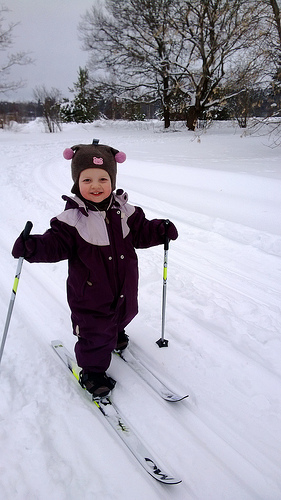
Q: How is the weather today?
A: It is foggy.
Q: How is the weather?
A: It is foggy.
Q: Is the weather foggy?
A: Yes, it is foggy.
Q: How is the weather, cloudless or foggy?
A: It is foggy.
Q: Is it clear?
A: No, it is foggy.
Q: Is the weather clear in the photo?
A: No, it is foggy.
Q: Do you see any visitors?
A: No, there are no visitors.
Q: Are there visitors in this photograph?
A: No, there are no visitors.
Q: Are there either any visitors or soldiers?
A: No, there are no visitors or soldiers.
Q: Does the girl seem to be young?
A: Yes, the girl is young.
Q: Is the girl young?
A: Yes, the girl is young.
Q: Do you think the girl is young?
A: Yes, the girl is young.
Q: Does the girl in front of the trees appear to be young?
A: Yes, the girl is young.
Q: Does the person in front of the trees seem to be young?
A: Yes, the girl is young.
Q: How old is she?
A: The girl is young.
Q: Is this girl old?
A: No, the girl is young.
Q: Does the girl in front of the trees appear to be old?
A: No, the girl is young.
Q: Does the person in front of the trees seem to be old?
A: No, the girl is young.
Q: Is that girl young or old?
A: The girl is young.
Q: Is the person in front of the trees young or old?
A: The girl is young.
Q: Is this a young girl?
A: Yes, this is a young girl.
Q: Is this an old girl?
A: No, this is a young girl.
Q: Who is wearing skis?
A: The girl is wearing skis.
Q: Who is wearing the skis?
A: The girl is wearing skis.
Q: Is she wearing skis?
A: Yes, the girl is wearing skis.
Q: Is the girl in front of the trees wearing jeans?
A: No, the girl is wearing skis.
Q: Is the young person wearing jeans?
A: No, the girl is wearing skis.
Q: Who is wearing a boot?
A: The girl is wearing a boot.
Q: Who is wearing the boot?
A: The girl is wearing a boot.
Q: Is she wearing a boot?
A: Yes, the girl is wearing a boot.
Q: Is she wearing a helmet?
A: No, the girl is wearing a boot.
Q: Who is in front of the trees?
A: The girl is in front of the trees.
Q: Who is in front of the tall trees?
A: The girl is in front of the trees.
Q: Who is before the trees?
A: The girl is in front of the trees.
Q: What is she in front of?
A: The girl is in front of the trees.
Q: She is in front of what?
A: The girl is in front of the trees.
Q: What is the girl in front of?
A: The girl is in front of the trees.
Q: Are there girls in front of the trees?
A: Yes, there is a girl in front of the trees.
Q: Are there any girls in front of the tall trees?
A: Yes, there is a girl in front of the trees.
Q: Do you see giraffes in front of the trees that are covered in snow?
A: No, there is a girl in front of the trees.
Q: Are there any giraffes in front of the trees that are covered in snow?
A: No, there is a girl in front of the trees.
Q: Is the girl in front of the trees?
A: Yes, the girl is in front of the trees.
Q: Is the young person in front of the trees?
A: Yes, the girl is in front of the trees.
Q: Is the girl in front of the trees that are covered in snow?
A: Yes, the girl is in front of the trees.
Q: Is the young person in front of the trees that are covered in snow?
A: Yes, the girl is in front of the trees.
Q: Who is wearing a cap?
A: The girl is wearing a cap.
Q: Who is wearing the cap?
A: The girl is wearing a cap.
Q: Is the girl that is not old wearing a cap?
A: Yes, the girl is wearing a cap.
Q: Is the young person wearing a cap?
A: Yes, the girl is wearing a cap.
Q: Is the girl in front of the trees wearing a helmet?
A: No, the girl is wearing a cap.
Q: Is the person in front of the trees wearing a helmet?
A: No, the girl is wearing a cap.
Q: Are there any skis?
A: Yes, there are skis.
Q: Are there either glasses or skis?
A: Yes, there are skis.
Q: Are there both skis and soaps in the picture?
A: No, there are skis but no soaps.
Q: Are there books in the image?
A: No, there are no books.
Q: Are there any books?
A: No, there are no books.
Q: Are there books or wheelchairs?
A: No, there are no books or wheelchairs.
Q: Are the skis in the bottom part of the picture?
A: Yes, the skis are in the bottom of the image.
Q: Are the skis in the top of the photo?
A: No, the skis are in the bottom of the image.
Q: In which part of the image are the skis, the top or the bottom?
A: The skis are in the bottom of the image.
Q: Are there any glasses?
A: No, there are no glasses.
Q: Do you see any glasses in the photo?
A: No, there are no glasses.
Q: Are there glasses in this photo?
A: No, there are no glasses.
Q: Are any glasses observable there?
A: No, there are no glasses.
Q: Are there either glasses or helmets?
A: No, there are no glasses or helmets.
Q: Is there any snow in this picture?
A: Yes, there is snow.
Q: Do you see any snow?
A: Yes, there is snow.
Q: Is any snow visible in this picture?
A: Yes, there is snow.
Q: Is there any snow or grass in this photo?
A: Yes, there is snow.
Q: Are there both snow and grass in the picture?
A: No, there is snow but no grass.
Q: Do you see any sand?
A: No, there is no sand.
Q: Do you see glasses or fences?
A: No, there are no fences or glasses.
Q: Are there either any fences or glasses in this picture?
A: No, there are no fences or glasses.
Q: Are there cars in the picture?
A: No, there are no cars.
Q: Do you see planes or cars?
A: No, there are no cars or planes.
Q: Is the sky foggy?
A: Yes, the sky is foggy.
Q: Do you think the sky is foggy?
A: Yes, the sky is foggy.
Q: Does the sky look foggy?
A: Yes, the sky is foggy.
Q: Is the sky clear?
A: No, the sky is foggy.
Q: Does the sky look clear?
A: No, the sky is foggy.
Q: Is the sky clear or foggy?
A: The sky is foggy.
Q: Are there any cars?
A: No, there are no cars.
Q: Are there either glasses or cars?
A: No, there are no cars or glasses.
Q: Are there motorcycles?
A: No, there are no motorcycles.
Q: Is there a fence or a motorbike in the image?
A: No, there are no motorcycles or fences.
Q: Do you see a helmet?
A: No, there are no helmets.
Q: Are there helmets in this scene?
A: No, there are no helmets.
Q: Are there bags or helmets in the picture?
A: No, there are no helmets or bags.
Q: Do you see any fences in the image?
A: No, there are no fences.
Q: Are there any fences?
A: No, there are no fences.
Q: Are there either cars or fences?
A: No, there are no fences or cars.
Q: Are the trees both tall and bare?
A: Yes, the trees are tall and bare.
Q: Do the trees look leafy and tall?
A: No, the trees are tall but bare.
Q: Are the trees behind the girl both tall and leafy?
A: No, the trees are tall but bare.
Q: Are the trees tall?
A: Yes, the trees are tall.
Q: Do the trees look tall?
A: Yes, the trees are tall.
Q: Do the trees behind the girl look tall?
A: Yes, the trees are tall.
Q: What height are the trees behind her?
A: The trees are tall.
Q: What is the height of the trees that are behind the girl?
A: The trees are tall.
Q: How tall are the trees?
A: The trees are tall.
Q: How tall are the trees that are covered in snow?
A: The trees are tall.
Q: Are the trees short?
A: No, the trees are tall.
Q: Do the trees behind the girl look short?
A: No, the trees are tall.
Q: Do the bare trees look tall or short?
A: The trees are tall.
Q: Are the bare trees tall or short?
A: The trees are tall.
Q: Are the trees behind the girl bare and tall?
A: Yes, the trees are bare and tall.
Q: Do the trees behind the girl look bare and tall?
A: Yes, the trees are bare and tall.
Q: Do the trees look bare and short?
A: No, the trees are bare but tall.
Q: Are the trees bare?
A: Yes, the trees are bare.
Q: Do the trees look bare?
A: Yes, the trees are bare.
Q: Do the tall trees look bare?
A: Yes, the trees are bare.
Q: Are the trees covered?
A: No, the trees are bare.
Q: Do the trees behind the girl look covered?
A: No, the trees are bare.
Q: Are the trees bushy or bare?
A: The trees are bare.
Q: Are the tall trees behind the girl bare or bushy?
A: The trees are bare.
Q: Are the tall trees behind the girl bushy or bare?
A: The trees are bare.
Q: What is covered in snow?
A: The trees are covered in snow.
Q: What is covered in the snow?
A: The trees are covered in snow.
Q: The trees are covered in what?
A: The trees are covered in snow.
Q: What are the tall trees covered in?
A: The trees are covered in snow.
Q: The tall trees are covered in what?
A: The trees are covered in snow.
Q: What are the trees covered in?
A: The trees are covered in snow.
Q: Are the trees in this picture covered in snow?
A: Yes, the trees are covered in snow.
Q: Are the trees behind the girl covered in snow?
A: Yes, the trees are covered in snow.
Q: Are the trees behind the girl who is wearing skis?
A: Yes, the trees are behind the girl.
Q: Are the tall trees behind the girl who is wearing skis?
A: Yes, the trees are behind the girl.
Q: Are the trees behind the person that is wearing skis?
A: Yes, the trees are behind the girl.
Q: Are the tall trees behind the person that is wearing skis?
A: Yes, the trees are behind the girl.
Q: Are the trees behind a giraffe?
A: No, the trees are behind the girl.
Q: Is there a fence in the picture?
A: No, there are no fences.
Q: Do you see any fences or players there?
A: No, there are no fences or players.